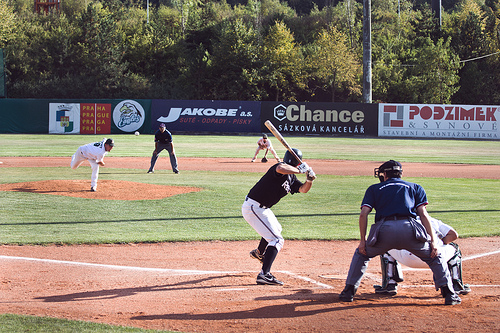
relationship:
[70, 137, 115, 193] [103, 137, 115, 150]
pitcher wearing cap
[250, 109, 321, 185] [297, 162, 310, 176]
bat in hand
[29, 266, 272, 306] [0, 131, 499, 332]
shadows on field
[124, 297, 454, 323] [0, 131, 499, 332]
shadow on field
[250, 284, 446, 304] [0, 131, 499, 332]
shadow on field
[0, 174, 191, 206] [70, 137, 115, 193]
mound of pitcher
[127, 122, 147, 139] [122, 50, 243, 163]
ball in air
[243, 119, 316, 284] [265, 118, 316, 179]
batter getting ready to swing bat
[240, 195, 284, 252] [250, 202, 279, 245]
pants with stripe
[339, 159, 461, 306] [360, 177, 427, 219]
ump wearing shirt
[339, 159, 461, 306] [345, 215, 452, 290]
ump wearing pants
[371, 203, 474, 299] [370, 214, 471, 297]
catcher wearing catcher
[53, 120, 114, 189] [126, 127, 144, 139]
pitcher just threw a ball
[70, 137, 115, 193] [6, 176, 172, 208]
pitcher on mound